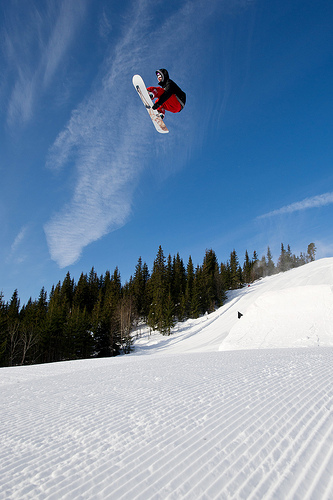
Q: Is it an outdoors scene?
A: Yes, it is outdoors.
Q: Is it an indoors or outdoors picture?
A: It is outdoors.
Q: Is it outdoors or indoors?
A: It is outdoors.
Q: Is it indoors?
A: No, it is outdoors.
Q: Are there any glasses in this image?
A: No, there are no glasses.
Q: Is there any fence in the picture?
A: No, there are no fences.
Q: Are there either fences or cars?
A: No, there are no fences or cars.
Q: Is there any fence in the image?
A: No, there are no fences.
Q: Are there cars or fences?
A: No, there are no fences or cars.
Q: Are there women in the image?
A: No, there are no women.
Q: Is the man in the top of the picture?
A: Yes, the man is in the top of the image.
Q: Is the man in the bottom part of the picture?
A: No, the man is in the top of the image.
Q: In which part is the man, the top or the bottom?
A: The man is in the top of the image.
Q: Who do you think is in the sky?
A: The man is in the sky.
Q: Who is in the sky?
A: The man is in the sky.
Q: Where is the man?
A: The man is in the sky.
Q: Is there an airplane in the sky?
A: No, there is a man in the sky.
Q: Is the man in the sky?
A: Yes, the man is in the sky.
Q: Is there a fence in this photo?
A: No, there are no fences.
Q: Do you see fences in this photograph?
A: No, there are no fences.